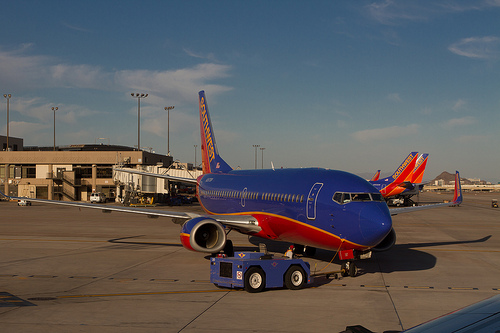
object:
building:
[0, 148, 174, 204]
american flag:
[385, 179, 389, 181]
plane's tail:
[387, 151, 418, 183]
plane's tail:
[412, 152, 429, 183]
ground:
[2, 190, 497, 328]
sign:
[236, 270, 243, 280]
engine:
[180, 216, 228, 253]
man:
[284, 245, 296, 259]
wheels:
[340, 262, 349, 277]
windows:
[300, 194, 304, 203]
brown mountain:
[424, 170, 475, 185]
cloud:
[0, 92, 99, 140]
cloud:
[447, 36, 500, 60]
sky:
[0, 1, 499, 181]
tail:
[112, 90, 232, 188]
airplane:
[368, 151, 418, 198]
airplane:
[369, 170, 381, 181]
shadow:
[106, 234, 493, 279]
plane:
[0, 90, 464, 277]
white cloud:
[308, 146, 373, 168]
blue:
[197, 90, 394, 247]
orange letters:
[199, 97, 218, 162]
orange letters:
[391, 153, 414, 179]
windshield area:
[332, 191, 385, 205]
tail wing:
[198, 89, 233, 174]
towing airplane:
[204, 227, 404, 299]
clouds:
[0, 41, 235, 110]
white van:
[90, 192, 107, 203]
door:
[306, 182, 324, 220]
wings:
[0, 192, 279, 242]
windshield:
[332, 191, 386, 206]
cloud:
[348, 121, 424, 145]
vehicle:
[210, 252, 311, 293]